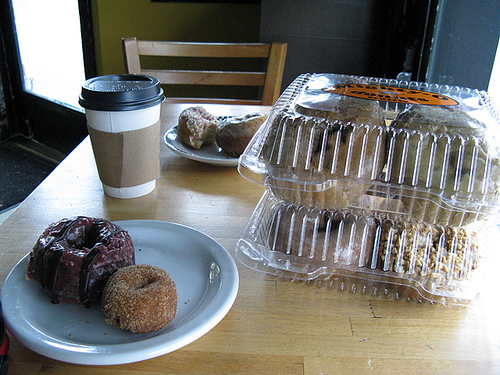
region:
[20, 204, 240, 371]
a white plate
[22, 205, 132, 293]
a dark brown donut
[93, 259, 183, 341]
a light brown donut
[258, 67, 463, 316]
two clear plastic containers of pastries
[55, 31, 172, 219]
a cup of coffee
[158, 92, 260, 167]
a plate of pastries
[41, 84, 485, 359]
a light brown table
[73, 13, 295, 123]
the top of a chair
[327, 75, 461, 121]
an orange bakery sticker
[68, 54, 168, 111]
a black coffee cup lid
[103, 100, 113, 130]
white cup with black top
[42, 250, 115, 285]
chocolate donut on plate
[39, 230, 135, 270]
chocolate frosted donut with icing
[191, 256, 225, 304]
white plate with 2 donuts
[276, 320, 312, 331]
table top is tan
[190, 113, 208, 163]
half eaten donut on plate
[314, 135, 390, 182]
clear container of bagels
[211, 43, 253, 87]
wooden chair by table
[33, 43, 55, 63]
clear window trimmed in brown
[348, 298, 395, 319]
black mark on the table top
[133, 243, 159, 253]
crumb on the white plate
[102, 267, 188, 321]
sugar covered donut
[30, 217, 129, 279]
chocolate frosting on donut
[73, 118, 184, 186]
brown covering on coffee cup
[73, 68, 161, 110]
black lid on coffee cup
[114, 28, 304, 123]
wood chair around table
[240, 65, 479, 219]
plastic container with muffins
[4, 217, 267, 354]
round white plate with treats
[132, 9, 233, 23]
yellow paint on the wall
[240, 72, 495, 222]
a package of donuts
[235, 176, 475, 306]
a package of donuts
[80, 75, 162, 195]
a plastic cup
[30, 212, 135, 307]
a red and black donut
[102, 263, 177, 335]
a sugar covered donut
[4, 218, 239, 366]
a blue plate with donuts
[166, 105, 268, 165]
a white plate with donuts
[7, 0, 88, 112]
the window on a dorr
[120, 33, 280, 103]
back of a wooden chair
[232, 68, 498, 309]
two plastic boxes of donuts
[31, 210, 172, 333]
two doughnuts on a plate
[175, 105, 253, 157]
two doughnuts on a plate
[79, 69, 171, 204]
a travel coffee cup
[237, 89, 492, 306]
two containers of doughnuts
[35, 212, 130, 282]
a chocolate covered doughnut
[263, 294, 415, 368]
a wooden table top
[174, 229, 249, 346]
a white plate on a table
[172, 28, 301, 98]
the back of a chair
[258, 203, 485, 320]
a plastic container filled with doughnuts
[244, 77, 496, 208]
a plastic container filled with doughnuts